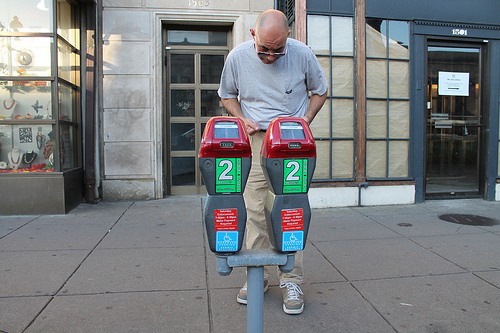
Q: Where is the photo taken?
A: City sidewalk.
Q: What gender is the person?
A: Male.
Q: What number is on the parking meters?
A: 2.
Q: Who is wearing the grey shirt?
A: The man.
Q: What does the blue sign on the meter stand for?
A: Handicap.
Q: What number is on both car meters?
A: Two.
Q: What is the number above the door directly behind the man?
A: 1503.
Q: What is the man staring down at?
A: The car meter.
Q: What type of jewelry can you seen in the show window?
A: Necklaces.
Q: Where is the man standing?
A: On the sidewalk.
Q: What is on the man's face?
A: Glasses.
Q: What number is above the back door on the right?
A: 1501.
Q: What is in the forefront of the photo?
A: The parking meters.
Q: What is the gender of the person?
A: Male.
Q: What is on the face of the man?
A: Glasses.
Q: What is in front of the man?
A: Parking meter.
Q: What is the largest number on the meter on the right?
A: 2.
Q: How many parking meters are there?
A: Two.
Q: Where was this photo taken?
A: London.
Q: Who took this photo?
A: The nun.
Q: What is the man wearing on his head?
A: Sunglasses.